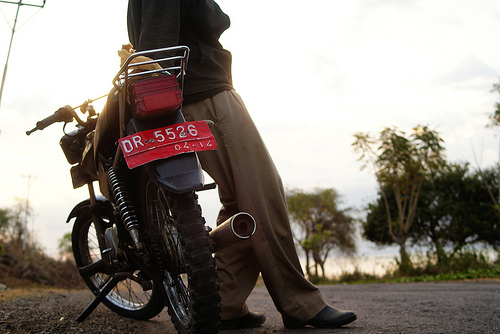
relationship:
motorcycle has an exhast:
[24, 44, 257, 331] [209, 211, 258, 255]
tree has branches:
[350, 122, 451, 280] [353, 172, 440, 236]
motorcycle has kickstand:
[24, 44, 257, 331] [73, 269, 139, 325]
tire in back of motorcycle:
[140, 160, 220, 333] [24, 44, 257, 331]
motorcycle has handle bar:
[24, 44, 257, 331] [26, 104, 90, 135]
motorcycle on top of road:
[24, 44, 257, 331] [2, 281, 500, 332]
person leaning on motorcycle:
[128, 0, 358, 333] [24, 44, 257, 331]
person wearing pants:
[128, 0, 358, 333] [181, 87, 329, 320]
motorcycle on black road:
[24, 44, 257, 331] [2, 281, 500, 332]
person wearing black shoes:
[128, 0, 358, 333] [224, 307, 360, 333]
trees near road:
[284, 75, 500, 281] [2, 281, 500, 332]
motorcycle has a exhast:
[24, 44, 257, 331] [209, 211, 258, 255]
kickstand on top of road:
[73, 269, 139, 325] [2, 281, 500, 332]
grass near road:
[313, 266, 500, 280] [2, 281, 500, 332]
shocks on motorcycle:
[105, 165, 143, 253] [24, 44, 257, 331]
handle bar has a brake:
[26, 104, 90, 135] [38, 113, 62, 129]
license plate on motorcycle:
[120, 117, 221, 168] [24, 44, 257, 331]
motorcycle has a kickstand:
[24, 44, 257, 331] [73, 269, 139, 325]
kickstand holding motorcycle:
[73, 269, 139, 325] [24, 44, 257, 331]